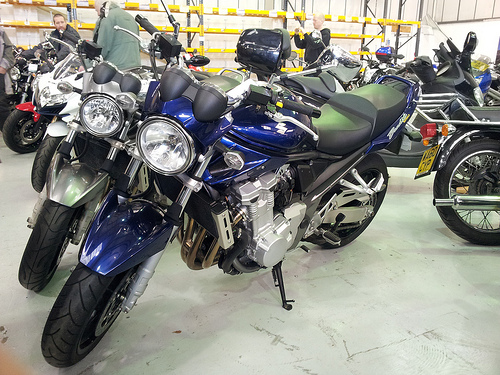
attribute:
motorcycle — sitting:
[0, 64, 175, 285]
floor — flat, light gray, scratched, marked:
[3, 153, 493, 371]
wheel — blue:
[35, 253, 140, 371]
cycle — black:
[36, 63, 426, 349]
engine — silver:
[213, 175, 327, 267]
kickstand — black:
[268, 264, 298, 314]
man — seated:
[42, 12, 83, 53]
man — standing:
[89, 1, 144, 73]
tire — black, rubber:
[9, 191, 87, 293]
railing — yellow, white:
[5, 0, 423, 84]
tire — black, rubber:
[39, 258, 129, 367]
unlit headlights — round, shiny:
[81, 88, 196, 176]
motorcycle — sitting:
[403, 31, 480, 105]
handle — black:
[283, 100, 320, 117]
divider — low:
[334, 90, 377, 139]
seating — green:
[354, 71, 407, 135]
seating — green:
[305, 97, 370, 156]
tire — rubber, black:
[438, 156, 468, 215]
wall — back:
[9, 0, 499, 78]